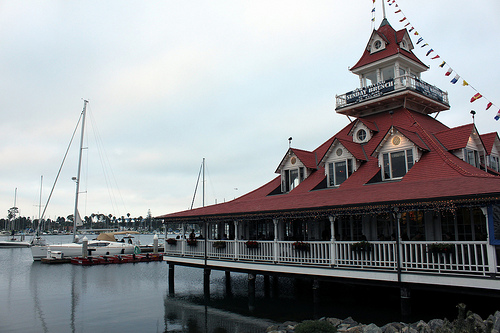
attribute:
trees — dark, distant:
[3, 213, 160, 232]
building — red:
[148, 0, 499, 299]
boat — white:
[25, 235, 141, 265]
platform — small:
[333, 74, 451, 118]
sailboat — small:
[4, 187, 30, 255]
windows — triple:
[319, 154, 357, 191]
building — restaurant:
[168, 37, 496, 294]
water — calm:
[0, 232, 497, 331]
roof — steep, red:
[158, 103, 497, 232]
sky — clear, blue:
[149, 57, 273, 149]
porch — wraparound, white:
[154, 231, 499, 311]